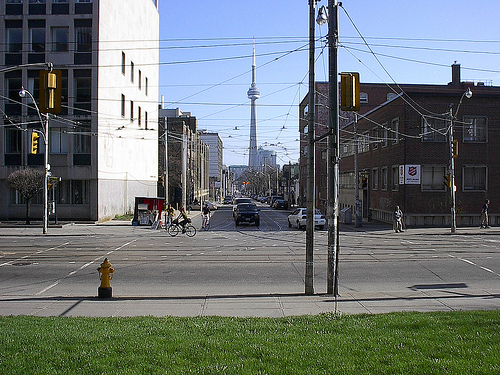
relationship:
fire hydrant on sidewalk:
[90, 253, 124, 304] [0, 288, 500, 315]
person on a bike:
[175, 205, 190, 227] [169, 216, 198, 238]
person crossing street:
[175, 205, 190, 227] [3, 235, 499, 291]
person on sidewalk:
[388, 198, 414, 234] [375, 215, 500, 233]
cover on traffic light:
[26, 130, 45, 158] [25, 124, 51, 157]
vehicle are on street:
[233, 203, 260, 226] [215, 192, 298, 234]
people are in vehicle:
[239, 205, 260, 218] [230, 200, 263, 229]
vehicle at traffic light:
[230, 200, 263, 229] [25, 124, 51, 157]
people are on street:
[162, 200, 219, 229] [159, 200, 313, 236]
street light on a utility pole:
[334, 69, 365, 113] [324, 4, 340, 299]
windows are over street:
[5, 0, 95, 207] [3, 235, 499, 291]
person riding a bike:
[175, 205, 190, 227] [169, 216, 198, 238]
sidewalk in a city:
[0, 288, 500, 315] [0, 2, 500, 373]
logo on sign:
[407, 164, 418, 181] [393, 161, 424, 187]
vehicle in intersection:
[230, 200, 263, 229] [15, 57, 476, 310]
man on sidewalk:
[473, 196, 495, 229] [375, 215, 500, 233]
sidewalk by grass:
[0, 288, 500, 315] [1, 314, 498, 374]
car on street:
[282, 202, 333, 231] [215, 192, 298, 234]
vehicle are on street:
[233, 203, 260, 226] [159, 200, 313, 236]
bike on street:
[169, 216, 198, 238] [3, 235, 499, 291]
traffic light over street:
[25, 124, 51, 157] [3, 235, 499, 291]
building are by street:
[247, 36, 261, 166] [3, 235, 499, 291]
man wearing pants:
[473, 196, 495, 229] [479, 211, 493, 231]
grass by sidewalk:
[1, 314, 498, 374] [0, 288, 500, 315]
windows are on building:
[110, 51, 165, 136] [239, 37, 267, 168]